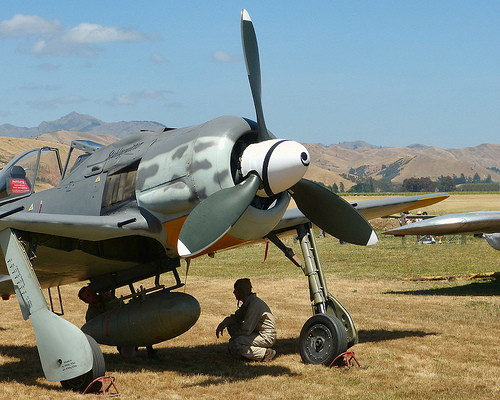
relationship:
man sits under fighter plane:
[216, 277, 277, 362] [0, 9, 453, 391]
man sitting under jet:
[192, 232, 316, 384] [1, 7, 451, 392]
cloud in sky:
[0, 0, 237, 121] [2, 2, 498, 142]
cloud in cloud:
[209, 47, 238, 62] [0, 0, 237, 121]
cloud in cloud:
[0, 0, 237, 121] [0, 0, 237, 121]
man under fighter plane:
[216, 277, 277, 362] [0, 9, 453, 391]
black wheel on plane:
[298, 314, 348, 366] [0, 4, 420, 323]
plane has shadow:
[381, 210, 499, 250] [381, 272, 499, 297]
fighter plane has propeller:
[0, 9, 453, 391] [126, 16, 433, 301]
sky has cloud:
[2, 2, 498, 142] [0, 0, 237, 121]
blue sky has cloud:
[342, 30, 468, 111] [0, 0, 237, 121]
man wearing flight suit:
[216, 277, 277, 362] [225, 290, 277, 360]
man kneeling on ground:
[216, 277, 277, 362] [0, 193, 497, 399]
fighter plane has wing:
[0, 9, 453, 391] [290, 179, 447, 249]